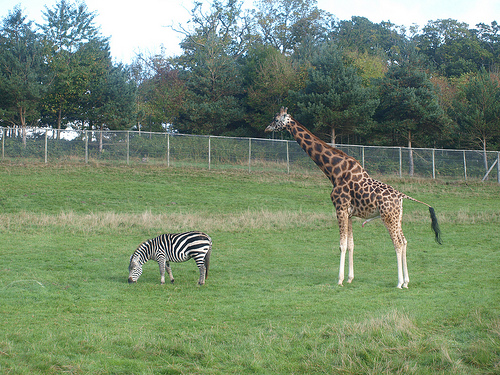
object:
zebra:
[127, 230, 213, 285]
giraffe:
[263, 106, 443, 289]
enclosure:
[0, 127, 499, 373]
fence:
[1, 133, 276, 176]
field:
[1, 163, 500, 373]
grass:
[2, 159, 499, 371]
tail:
[409, 192, 445, 238]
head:
[126, 257, 144, 283]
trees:
[0, 0, 125, 129]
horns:
[278, 106, 285, 116]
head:
[263, 103, 293, 135]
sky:
[1, 1, 499, 73]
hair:
[426, 205, 444, 244]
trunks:
[16, 120, 33, 154]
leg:
[336, 212, 347, 287]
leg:
[346, 219, 354, 282]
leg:
[390, 223, 403, 289]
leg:
[403, 223, 410, 288]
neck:
[289, 118, 352, 182]